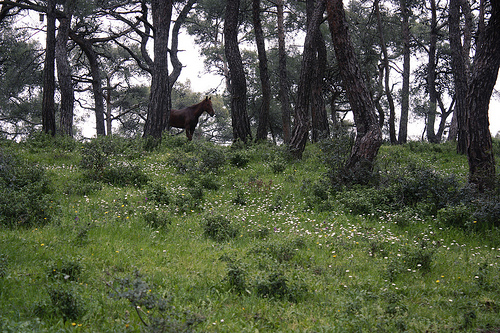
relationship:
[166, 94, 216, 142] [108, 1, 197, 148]
horse behind tree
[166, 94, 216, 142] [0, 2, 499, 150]
horse in front of sky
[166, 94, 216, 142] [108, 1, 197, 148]
horse by a tree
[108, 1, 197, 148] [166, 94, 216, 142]
tree in front of horse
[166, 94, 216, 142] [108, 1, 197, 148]
horse standing by tree